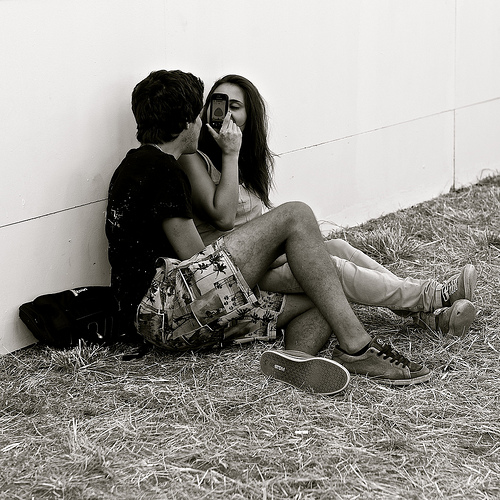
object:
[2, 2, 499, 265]
wall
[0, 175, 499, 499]
grass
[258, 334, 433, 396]
shoes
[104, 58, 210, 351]
boy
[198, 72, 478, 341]
girl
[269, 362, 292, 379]
sole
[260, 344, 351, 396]
shoe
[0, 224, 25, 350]
part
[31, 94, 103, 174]
wall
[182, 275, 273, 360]
part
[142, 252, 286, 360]
short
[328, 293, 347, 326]
part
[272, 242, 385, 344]
leg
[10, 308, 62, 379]
part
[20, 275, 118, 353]
bag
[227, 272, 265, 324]
edge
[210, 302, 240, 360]
short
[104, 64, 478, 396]
couple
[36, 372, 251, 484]
grass